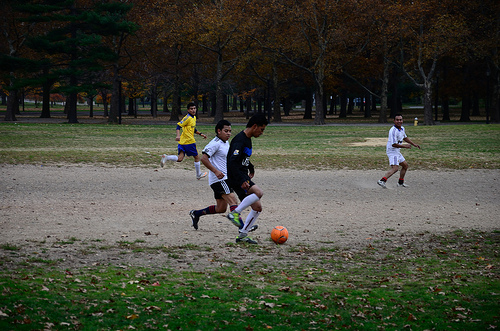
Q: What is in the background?
A: Trees.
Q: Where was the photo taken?
A: At a park.